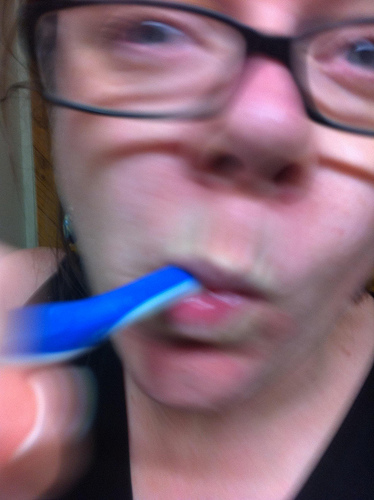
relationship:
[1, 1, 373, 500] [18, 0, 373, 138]
person wearing glasses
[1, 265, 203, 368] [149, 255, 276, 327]
toothbrush in persons mouth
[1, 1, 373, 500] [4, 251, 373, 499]
person wearing black top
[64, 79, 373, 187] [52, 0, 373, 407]
shadow on top of face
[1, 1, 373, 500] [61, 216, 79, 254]
person wearing earring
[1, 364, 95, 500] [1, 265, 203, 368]
fingers holding toothbrush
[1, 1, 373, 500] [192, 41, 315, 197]
person has a nose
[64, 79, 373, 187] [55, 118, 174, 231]
shadow over cheek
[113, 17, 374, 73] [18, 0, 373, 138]
eyes behind glasses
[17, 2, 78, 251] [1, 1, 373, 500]
doorway behind person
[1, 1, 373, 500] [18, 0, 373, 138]
person wears glasses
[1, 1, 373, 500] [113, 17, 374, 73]
person with blue eyes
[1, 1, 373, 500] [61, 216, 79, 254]
person with earring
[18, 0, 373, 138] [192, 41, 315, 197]
glasses are on top of nose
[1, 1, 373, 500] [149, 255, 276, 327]
person with a toothbrush in mouth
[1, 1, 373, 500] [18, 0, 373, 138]
person using glasses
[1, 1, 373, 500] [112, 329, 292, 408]
person has chin